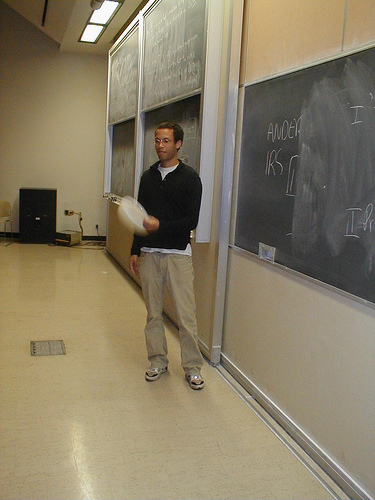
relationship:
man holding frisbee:
[116, 108, 215, 399] [107, 191, 154, 239]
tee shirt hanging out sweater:
[138, 246, 194, 258] [114, 158, 212, 257]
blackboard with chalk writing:
[233, 43, 373, 303] [251, 96, 374, 239]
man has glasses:
[116, 108, 215, 399] [148, 133, 178, 150]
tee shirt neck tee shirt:
[154, 161, 179, 173] [157, 161, 173, 174]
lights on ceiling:
[68, 1, 124, 52] [0, 0, 143, 54]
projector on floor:
[53, 205, 89, 249] [3, 236, 131, 496]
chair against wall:
[2, 189, 21, 241] [1, 53, 100, 242]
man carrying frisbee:
[116, 108, 215, 399] [107, 191, 154, 239]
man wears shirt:
[116, 108, 215, 399] [114, 158, 212, 257]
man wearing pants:
[116, 108, 215, 399] [130, 245, 207, 369]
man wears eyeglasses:
[116, 108, 215, 399] [148, 133, 178, 150]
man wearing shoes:
[116, 108, 215, 399] [136, 358, 215, 399]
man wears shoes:
[116, 108, 215, 399] [136, 358, 215, 399]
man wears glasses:
[116, 108, 215, 399] [148, 133, 178, 150]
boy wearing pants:
[116, 108, 215, 399] [130, 245, 207, 369]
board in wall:
[233, 43, 373, 303] [209, 0, 374, 482]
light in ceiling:
[68, 1, 124, 52] [0, 0, 143, 54]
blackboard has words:
[233, 43, 373, 303] [251, 96, 374, 239]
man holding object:
[116, 108, 215, 399] [107, 191, 154, 239]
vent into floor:
[31, 333, 70, 361] [3, 236, 131, 496]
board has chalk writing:
[233, 43, 373, 303] [251, 96, 374, 239]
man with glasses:
[116, 108, 215, 399] [148, 133, 178, 150]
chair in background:
[2, 189, 21, 241] [1, 53, 100, 242]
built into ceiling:
[68, 1, 124, 52] [0, 0, 143, 54]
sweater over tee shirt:
[114, 158, 212, 257] [138, 246, 194, 255]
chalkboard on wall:
[233, 43, 373, 303] [209, 0, 374, 482]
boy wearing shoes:
[136, 358, 215, 399] [144, 360, 205, 389]